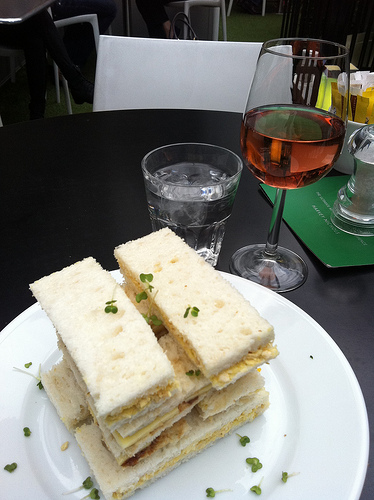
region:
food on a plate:
[39, 206, 279, 498]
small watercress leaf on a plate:
[244, 454, 266, 474]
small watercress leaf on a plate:
[198, 485, 235, 498]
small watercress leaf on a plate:
[234, 428, 253, 449]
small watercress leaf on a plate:
[275, 467, 303, 485]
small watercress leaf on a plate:
[21, 423, 33, 440]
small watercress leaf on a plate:
[3, 458, 22, 476]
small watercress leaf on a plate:
[59, 471, 94, 497]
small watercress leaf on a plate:
[78, 484, 98, 498]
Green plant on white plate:
[231, 430, 260, 448]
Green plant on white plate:
[240, 449, 261, 474]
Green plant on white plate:
[276, 466, 297, 489]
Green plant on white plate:
[244, 476, 267, 496]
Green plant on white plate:
[196, 477, 228, 498]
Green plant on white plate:
[18, 416, 33, 436]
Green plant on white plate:
[66, 469, 92, 486]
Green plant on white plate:
[78, 489, 102, 498]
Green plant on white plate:
[2, 453, 23, 477]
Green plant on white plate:
[12, 342, 47, 399]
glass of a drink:
[227, 30, 355, 295]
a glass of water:
[134, 131, 251, 271]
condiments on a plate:
[196, 426, 306, 498]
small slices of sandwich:
[29, 210, 294, 498]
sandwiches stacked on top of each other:
[26, 197, 292, 494]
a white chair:
[93, 30, 298, 127]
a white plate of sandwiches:
[0, 236, 366, 498]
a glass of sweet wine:
[226, 32, 354, 298]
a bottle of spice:
[331, 114, 372, 230]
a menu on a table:
[253, 152, 372, 271]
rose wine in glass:
[223, 33, 357, 304]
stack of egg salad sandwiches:
[23, 220, 300, 498]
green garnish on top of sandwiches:
[91, 271, 200, 334]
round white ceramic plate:
[2, 252, 371, 498]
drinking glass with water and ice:
[135, 139, 246, 278]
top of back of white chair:
[87, 28, 302, 121]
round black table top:
[0, 104, 372, 498]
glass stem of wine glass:
[262, 182, 287, 257]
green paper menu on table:
[256, 167, 373, 284]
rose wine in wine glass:
[238, 102, 346, 191]